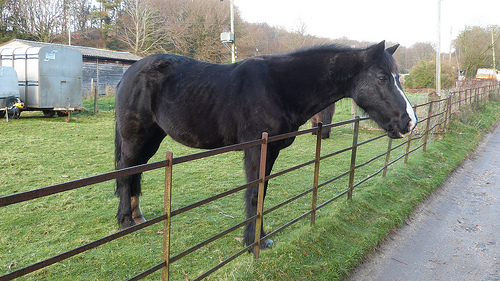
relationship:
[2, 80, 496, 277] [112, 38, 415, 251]
fence in front of horse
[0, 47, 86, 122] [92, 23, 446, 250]
trailer behind horse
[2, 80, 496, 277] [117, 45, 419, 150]
fence in front of horse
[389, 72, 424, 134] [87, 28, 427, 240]
patch on horse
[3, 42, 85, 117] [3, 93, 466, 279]
trailer in field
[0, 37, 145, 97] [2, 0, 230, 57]
building by trees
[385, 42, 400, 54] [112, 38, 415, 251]
ear on horse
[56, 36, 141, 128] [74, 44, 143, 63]
building has roof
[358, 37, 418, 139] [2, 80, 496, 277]
head leaning over fence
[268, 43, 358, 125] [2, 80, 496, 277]
neck leaning over fence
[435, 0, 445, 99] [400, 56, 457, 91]
pole in front of bush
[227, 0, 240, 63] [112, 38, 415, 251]
pole behind horse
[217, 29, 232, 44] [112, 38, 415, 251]
metal box behind horse